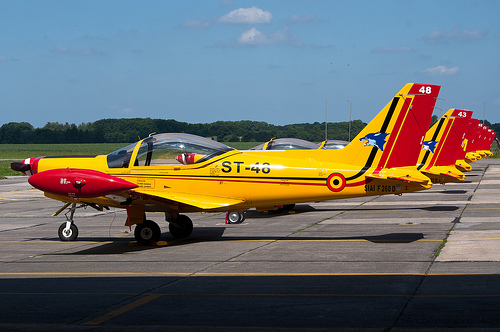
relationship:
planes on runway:
[23, 81, 499, 235] [2, 151, 500, 330]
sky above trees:
[2, 0, 499, 124] [2, 118, 500, 147]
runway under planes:
[2, 151, 500, 330] [23, 81, 499, 235]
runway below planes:
[2, 151, 500, 330] [23, 81, 499, 235]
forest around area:
[2, 115, 498, 144] [1, 140, 497, 330]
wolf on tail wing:
[357, 130, 392, 155] [364, 81, 440, 168]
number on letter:
[252, 158, 271, 176] [229, 159, 247, 175]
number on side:
[252, 158, 271, 176] [17, 147, 420, 196]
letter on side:
[214, 159, 234, 174] [17, 147, 420, 196]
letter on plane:
[214, 159, 234, 174] [7, 79, 439, 249]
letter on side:
[229, 159, 247, 175] [17, 147, 420, 196]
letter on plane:
[229, 159, 247, 175] [7, 79, 439, 249]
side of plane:
[17, 147, 420, 196] [7, 79, 439, 249]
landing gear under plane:
[56, 204, 196, 251] [7, 79, 439, 249]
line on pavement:
[68, 288, 167, 330] [0, 169, 499, 329]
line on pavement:
[3, 264, 423, 279] [0, 169, 499, 329]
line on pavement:
[6, 236, 367, 245] [0, 169, 499, 329]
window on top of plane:
[105, 127, 237, 171] [7, 79, 439, 249]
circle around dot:
[330, 176, 340, 187] [333, 179, 339, 185]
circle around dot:
[320, 172, 348, 192] [333, 179, 339, 185]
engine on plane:
[21, 169, 136, 201] [7, 79, 439, 249]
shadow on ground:
[22, 222, 424, 255] [0, 155, 498, 331]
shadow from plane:
[22, 222, 424, 255] [7, 79, 439, 249]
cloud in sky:
[219, 2, 273, 25] [2, 0, 499, 124]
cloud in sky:
[231, 28, 265, 48] [2, 0, 499, 124]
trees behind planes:
[0, 110, 499, 142] [23, 81, 499, 235]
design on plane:
[324, 169, 347, 193] [7, 79, 439, 249]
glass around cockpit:
[107, 129, 232, 165] [95, 133, 244, 177]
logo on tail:
[176, 149, 293, 199] [311, 15, 461, 235]